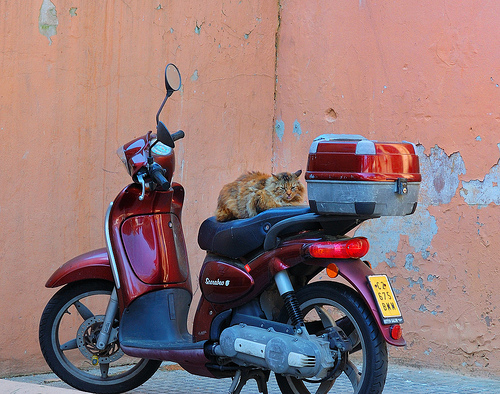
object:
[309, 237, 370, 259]
light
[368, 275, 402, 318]
plate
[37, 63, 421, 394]
scooter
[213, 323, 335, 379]
drive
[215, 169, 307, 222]
cat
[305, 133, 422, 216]
luggage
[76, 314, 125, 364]
disc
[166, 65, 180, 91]
mirror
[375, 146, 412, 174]
paint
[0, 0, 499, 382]
wall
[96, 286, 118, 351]
shock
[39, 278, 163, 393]
tire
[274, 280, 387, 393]
tire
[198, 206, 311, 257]
seat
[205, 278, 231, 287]
lettering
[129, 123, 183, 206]
bars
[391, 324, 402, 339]
circle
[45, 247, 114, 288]
fender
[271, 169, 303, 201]
head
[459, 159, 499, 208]
chips